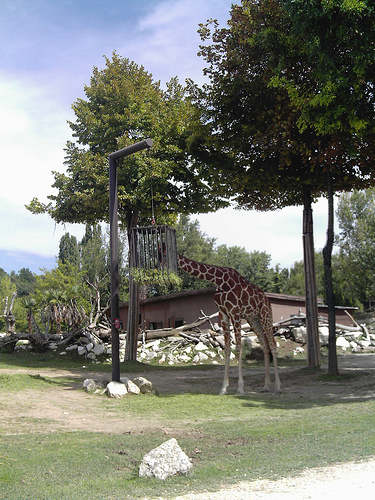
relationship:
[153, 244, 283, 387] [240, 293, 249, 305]
giraffe has spots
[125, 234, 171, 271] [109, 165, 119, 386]
feeder on pole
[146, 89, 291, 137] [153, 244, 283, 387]
trees behind giraffe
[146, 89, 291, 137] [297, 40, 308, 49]
trees have leaves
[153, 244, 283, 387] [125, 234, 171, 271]
giraffe eating from feeder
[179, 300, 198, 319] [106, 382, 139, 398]
building behind rocks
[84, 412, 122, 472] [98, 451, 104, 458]
ground has grass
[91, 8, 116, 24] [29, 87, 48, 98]
sky has clouds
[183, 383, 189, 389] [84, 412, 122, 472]
shadow on ground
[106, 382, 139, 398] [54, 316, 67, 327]
rocks on hill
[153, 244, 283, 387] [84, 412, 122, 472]
giraffe on ground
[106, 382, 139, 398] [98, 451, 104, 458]
rocks on grass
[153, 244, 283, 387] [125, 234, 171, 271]
giraffe using feeder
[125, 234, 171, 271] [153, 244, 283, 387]
feeder for giraffe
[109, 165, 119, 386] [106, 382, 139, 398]
pole near rocks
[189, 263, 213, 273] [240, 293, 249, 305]
neck has spots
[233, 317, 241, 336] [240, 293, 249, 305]
legs have spots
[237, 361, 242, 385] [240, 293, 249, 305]
lower half no spots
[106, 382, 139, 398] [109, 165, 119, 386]
rocks near pole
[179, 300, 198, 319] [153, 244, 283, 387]
building behind giraffe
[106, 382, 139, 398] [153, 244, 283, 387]
rocks behind giraffe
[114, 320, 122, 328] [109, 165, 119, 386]
item on pole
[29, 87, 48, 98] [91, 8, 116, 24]
clouds in sky